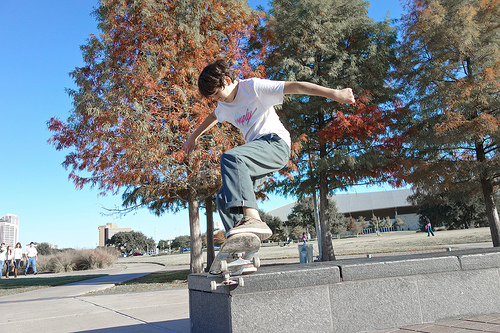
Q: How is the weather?
A: It is clear.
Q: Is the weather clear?
A: Yes, it is clear.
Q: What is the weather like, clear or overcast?
A: It is clear.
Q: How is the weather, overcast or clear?
A: It is clear.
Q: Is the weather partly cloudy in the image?
A: No, it is clear.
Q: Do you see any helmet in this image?
A: No, there are no helmets.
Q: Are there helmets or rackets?
A: No, there are no helmets or rackets.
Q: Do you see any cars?
A: No, there are no cars.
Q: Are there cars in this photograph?
A: No, there are no cars.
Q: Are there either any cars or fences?
A: No, there are no cars or fences.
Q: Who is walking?
A: The people are walking.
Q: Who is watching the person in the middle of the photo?
A: The people are watching the boy.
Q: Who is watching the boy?
A: The people are watching the boy.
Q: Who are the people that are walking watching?
A: The people are watching the boy.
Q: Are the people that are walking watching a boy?
A: Yes, the people are watching a boy.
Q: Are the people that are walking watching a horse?
A: No, the people are watching a boy.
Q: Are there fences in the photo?
A: No, there are no fences.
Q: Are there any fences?
A: No, there are no fences.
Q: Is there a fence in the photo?
A: No, there are no fences.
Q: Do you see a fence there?
A: No, there are no fences.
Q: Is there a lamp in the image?
A: No, there are no lamps.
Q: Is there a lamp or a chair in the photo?
A: No, there are no lamps or chairs.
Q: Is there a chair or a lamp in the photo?
A: No, there are no lamps or chairs.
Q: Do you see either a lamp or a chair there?
A: No, there are no lamps or chairs.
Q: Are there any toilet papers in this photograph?
A: No, there are no toilet papers.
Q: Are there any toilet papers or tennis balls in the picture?
A: No, there are no toilet papers or tennis balls.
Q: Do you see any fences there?
A: No, there are no fences.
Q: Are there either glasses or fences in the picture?
A: No, there are no fences or glasses.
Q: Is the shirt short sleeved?
A: Yes, the shirt is short sleeved.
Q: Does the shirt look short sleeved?
A: Yes, the shirt is short sleeved.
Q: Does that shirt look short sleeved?
A: Yes, the shirt is short sleeved.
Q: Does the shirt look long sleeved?
A: No, the shirt is short sleeved.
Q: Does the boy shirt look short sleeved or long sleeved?
A: The shirt is short sleeved.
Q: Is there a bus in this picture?
A: No, there are no buses.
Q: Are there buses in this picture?
A: No, there are no buses.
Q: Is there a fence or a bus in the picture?
A: No, there are no buses or fences.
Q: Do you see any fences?
A: No, there are no fences.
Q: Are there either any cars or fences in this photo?
A: No, there are no fences or cars.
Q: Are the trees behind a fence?
A: No, the trees are behind the boy.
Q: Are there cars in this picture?
A: No, there are no cars.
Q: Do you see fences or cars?
A: No, there are no cars or fences.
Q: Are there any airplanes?
A: No, there are no airplanes.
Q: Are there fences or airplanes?
A: No, there are no airplanes or fences.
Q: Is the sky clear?
A: Yes, the sky is clear.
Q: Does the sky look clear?
A: Yes, the sky is clear.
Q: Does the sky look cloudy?
A: No, the sky is clear.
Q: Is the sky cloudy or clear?
A: The sky is clear.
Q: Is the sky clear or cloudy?
A: The sky is clear.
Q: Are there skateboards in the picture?
A: Yes, there is a skateboard.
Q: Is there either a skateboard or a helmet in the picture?
A: Yes, there is a skateboard.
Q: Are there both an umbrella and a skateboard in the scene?
A: No, there is a skateboard but no umbrellas.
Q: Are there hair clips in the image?
A: No, there are no hair clips.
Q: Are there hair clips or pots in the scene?
A: No, there are no hair clips or pots.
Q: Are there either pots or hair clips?
A: No, there are no hair clips or pots.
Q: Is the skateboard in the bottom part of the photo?
A: Yes, the skateboard is in the bottom of the image.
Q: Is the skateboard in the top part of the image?
A: No, the skateboard is in the bottom of the image.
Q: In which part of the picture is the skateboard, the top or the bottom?
A: The skateboard is in the bottom of the image.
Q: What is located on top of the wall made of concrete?
A: The skateboard is on top of the wall.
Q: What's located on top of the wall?
A: The skateboard is on top of the wall.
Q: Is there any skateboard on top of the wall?
A: Yes, there is a skateboard on top of the wall.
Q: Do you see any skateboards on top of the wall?
A: Yes, there is a skateboard on top of the wall.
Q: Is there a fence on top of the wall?
A: No, there is a skateboard on top of the wall.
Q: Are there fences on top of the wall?
A: No, there is a skateboard on top of the wall.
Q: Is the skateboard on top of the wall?
A: Yes, the skateboard is on top of the wall.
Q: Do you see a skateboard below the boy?
A: Yes, there is a skateboard below the boy.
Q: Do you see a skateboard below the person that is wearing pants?
A: Yes, there is a skateboard below the boy.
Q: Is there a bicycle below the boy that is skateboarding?
A: No, there is a skateboard below the boy.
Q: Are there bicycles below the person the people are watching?
A: No, there is a skateboard below the boy.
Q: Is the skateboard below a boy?
A: Yes, the skateboard is below a boy.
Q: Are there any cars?
A: No, there are no cars.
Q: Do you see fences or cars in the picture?
A: No, there are no cars or fences.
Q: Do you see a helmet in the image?
A: No, there are no helmets.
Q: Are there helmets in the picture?
A: No, there are no helmets.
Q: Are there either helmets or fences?
A: No, there are no helmets or fences.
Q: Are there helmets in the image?
A: No, there are no helmets.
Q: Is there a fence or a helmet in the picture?
A: No, there are no helmets or fences.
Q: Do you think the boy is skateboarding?
A: Yes, the boy is skateboarding.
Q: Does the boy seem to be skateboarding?
A: Yes, the boy is skateboarding.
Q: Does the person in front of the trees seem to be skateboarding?
A: Yes, the boy is skateboarding.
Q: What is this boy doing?
A: The boy is skateboarding.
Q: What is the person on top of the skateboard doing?
A: The boy is skateboarding.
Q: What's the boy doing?
A: The boy is skateboarding.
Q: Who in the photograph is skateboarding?
A: The boy is skateboarding.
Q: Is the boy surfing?
A: No, the boy is skateboarding.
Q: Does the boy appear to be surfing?
A: No, the boy is skateboarding.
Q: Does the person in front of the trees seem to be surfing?
A: No, the boy is skateboarding.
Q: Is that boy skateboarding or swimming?
A: The boy is skateboarding.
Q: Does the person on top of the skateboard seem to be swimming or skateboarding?
A: The boy is skateboarding.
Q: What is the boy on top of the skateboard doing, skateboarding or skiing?
A: The boy is skateboarding.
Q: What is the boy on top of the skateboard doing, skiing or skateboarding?
A: The boy is skateboarding.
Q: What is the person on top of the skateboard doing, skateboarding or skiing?
A: The boy is skateboarding.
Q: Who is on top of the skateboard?
A: The boy is on top of the skateboard.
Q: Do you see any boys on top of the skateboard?
A: Yes, there is a boy on top of the skateboard.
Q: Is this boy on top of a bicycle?
A: No, the boy is on top of the skateboard.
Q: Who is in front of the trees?
A: The boy is in front of the trees.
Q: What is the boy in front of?
A: The boy is in front of the trees.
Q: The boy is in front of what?
A: The boy is in front of the trees.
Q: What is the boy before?
A: The boy is in front of the trees.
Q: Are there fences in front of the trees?
A: No, there is a boy in front of the trees.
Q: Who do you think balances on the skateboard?
A: The boy balances on the skateboard.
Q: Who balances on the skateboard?
A: The boy balances on the skateboard.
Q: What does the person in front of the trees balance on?
A: The boy balances on the skateboard.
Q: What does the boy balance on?
A: The boy balances on the skateboard.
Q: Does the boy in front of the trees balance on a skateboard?
A: Yes, the boy balances on a skateboard.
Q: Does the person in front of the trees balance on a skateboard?
A: Yes, the boy balances on a skateboard.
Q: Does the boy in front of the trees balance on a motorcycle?
A: No, the boy balances on a skateboard.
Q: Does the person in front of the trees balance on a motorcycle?
A: No, the boy balances on a skateboard.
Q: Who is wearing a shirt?
A: The boy is wearing a shirt.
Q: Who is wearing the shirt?
A: The boy is wearing a shirt.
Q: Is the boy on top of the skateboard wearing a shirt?
A: Yes, the boy is wearing a shirt.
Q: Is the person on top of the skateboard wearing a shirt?
A: Yes, the boy is wearing a shirt.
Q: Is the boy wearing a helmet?
A: No, the boy is wearing a shirt.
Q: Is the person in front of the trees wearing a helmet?
A: No, the boy is wearing a shirt.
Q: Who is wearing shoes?
A: The boy is wearing shoes.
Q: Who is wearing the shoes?
A: The boy is wearing shoes.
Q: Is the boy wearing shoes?
A: Yes, the boy is wearing shoes.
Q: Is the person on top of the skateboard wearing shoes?
A: Yes, the boy is wearing shoes.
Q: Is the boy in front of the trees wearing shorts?
A: No, the boy is wearing shoes.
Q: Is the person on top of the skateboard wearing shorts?
A: No, the boy is wearing shoes.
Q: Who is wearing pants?
A: The boy is wearing pants.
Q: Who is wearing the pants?
A: The boy is wearing pants.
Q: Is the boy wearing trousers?
A: Yes, the boy is wearing trousers.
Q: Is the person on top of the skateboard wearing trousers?
A: Yes, the boy is wearing trousers.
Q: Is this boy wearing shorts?
A: No, the boy is wearing trousers.